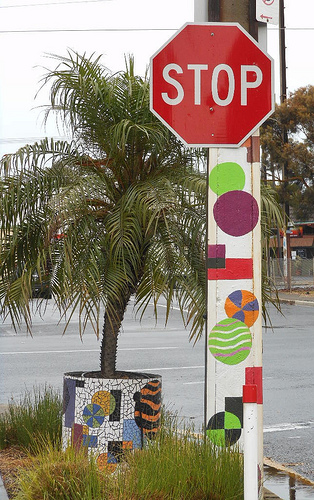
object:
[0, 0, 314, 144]
sky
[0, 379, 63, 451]
grass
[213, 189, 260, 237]
circle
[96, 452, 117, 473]
design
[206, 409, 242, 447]
circle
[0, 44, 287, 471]
palm tree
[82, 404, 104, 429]
design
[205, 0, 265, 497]
pole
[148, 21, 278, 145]
top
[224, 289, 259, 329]
circle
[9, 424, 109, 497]
grass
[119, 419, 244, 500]
grass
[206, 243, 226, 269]
square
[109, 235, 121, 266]
leaves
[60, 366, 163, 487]
post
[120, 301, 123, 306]
spines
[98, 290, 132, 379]
tree trunk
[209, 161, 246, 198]
circle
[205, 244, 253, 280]
design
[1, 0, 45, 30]
cloud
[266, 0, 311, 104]
cloud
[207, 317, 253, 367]
circle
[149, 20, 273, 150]
sign